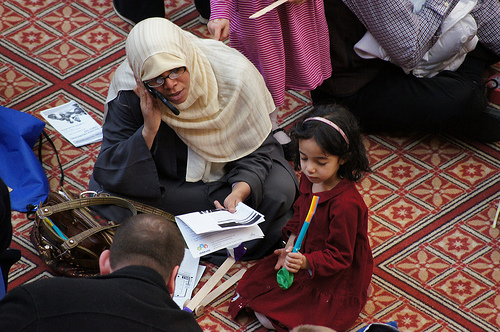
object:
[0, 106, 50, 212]
bag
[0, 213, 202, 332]
man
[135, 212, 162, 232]
bald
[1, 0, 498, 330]
ground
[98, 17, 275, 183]
cloth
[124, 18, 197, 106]
head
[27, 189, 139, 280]
purse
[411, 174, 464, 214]
pattern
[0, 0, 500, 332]
carpet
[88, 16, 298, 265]
woman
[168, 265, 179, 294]
ear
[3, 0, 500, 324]
floor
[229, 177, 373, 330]
dress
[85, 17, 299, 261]
person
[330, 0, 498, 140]
man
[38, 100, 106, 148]
brochure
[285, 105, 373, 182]
hair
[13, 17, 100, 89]
burka rug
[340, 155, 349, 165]
ear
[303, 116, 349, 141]
head band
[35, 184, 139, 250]
handle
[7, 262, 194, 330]
shirt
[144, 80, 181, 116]
phone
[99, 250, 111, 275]
ear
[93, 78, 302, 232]
burka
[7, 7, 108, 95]
pattern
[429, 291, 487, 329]
pattern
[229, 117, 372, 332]
child